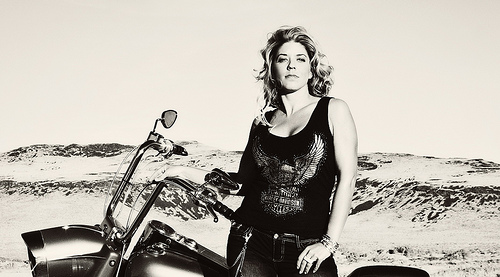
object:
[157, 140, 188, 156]
handle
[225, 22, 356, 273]
woman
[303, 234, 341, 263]
hip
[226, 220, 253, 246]
hip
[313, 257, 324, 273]
finger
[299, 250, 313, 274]
finger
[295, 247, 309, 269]
finger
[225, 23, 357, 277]
person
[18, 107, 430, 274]
vehicle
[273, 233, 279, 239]
button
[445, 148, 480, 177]
ground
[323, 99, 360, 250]
arm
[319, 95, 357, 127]
shoulder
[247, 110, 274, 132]
shoulder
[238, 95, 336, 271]
black tank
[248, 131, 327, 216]
eagle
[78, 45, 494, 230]
woman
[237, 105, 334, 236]
shirt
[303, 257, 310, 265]
ring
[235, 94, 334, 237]
tank top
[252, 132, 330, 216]
eagle design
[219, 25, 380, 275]
woman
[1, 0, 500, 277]
black/white shot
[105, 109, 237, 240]
handlebars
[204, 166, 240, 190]
mirror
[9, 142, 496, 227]
hill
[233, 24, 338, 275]
woman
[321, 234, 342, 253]
bracelet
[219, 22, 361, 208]
woman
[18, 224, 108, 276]
cover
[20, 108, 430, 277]
motorcycle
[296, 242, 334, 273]
hand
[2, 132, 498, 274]
terrain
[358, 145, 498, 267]
mountains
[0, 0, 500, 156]
sky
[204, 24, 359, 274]
woman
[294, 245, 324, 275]
fingers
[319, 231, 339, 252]
wrist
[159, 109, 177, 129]
mirror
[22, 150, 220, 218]
snow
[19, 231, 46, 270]
light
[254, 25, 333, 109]
hair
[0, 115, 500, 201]
distance